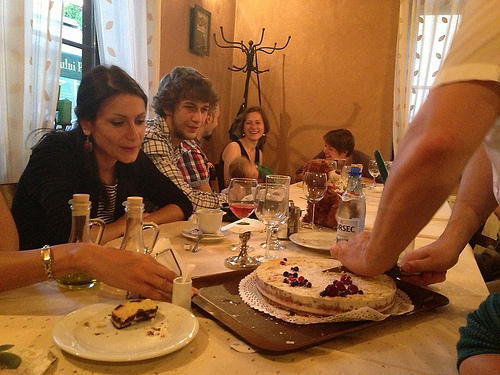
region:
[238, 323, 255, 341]
par tof a tray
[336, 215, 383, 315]
part if a hand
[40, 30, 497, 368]
Family sitting around dinner table.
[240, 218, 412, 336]
A person slicing a pie.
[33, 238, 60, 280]
Watch on a woman's wrist.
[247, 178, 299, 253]
An empty wine glass.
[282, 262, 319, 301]
Fruit on a pie.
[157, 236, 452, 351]
Tray holding a pie.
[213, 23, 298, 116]
Coat rack in the corner.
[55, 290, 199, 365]
A white circular plate.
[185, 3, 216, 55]
Picture hanging on the wall.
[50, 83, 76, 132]
Candle in the window seal.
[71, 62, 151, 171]
the head of a woman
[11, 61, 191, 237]
a woman wearing black sitting at table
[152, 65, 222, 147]
the head of a man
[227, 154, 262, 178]
the head of a baby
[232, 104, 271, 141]
the head of a woman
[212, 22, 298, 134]
a purse hanging on a coat rack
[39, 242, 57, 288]
a bracelet on an arm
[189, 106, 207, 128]
the nose of a man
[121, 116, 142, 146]
the nose of a woman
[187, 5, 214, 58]
a picture in frame hanging on a wall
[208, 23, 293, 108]
black coat rack in the corner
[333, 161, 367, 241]
clear and blue bottle of water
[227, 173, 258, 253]
glass of pink wine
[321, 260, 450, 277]
silver cutting knife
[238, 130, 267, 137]
woman wearing earrings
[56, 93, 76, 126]
green candle in the window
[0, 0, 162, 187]
white curtains on the window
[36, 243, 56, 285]
silver watch on the arm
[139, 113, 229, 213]
white and black plaid shirt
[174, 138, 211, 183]
red, white and blue plaid shirt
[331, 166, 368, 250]
Clear bottle with blue top.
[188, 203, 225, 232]
White coffee cup on table.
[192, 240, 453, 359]
A brown tray with a dessert on it.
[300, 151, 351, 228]
Brown stuffed toy on table.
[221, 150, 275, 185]
Child that is being held by a woman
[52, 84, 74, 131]
Green candles in a window.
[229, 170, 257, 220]
Wine glass with red wine.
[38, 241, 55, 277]
Thin gold women's watch.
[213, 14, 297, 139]
Dark coat rack in corner.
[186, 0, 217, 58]
Picture hung on wall.